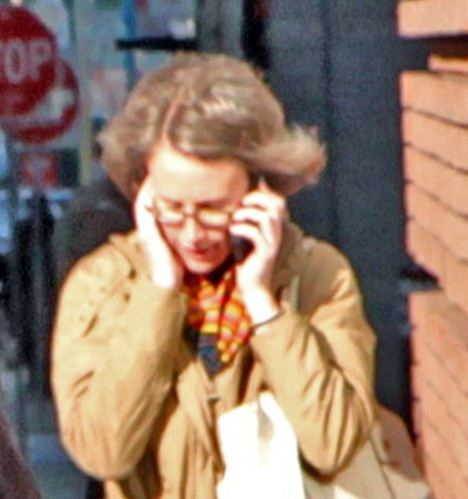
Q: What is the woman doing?
A: Talking on a phone.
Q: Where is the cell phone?
A: In the woman's left hand.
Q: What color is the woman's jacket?
A: Tan.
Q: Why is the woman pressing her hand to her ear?
A: To hear better.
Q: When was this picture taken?
A: Daytime.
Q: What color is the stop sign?
A: Red.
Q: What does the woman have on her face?
A: Glasses.